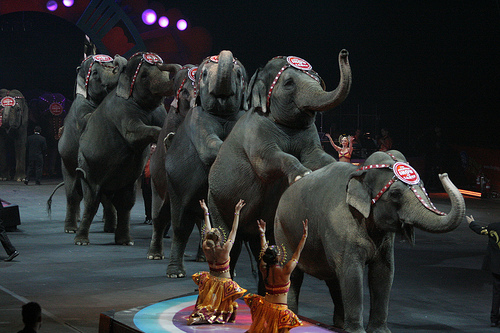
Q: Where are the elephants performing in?
A: A circus.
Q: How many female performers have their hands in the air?
A: 3.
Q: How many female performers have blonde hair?
A: 1.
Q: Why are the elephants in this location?
A: They are circus performers.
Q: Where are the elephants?
A: At the circus.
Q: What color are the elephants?
A: Gray.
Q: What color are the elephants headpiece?
A: Red and white.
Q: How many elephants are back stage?
A: 2.